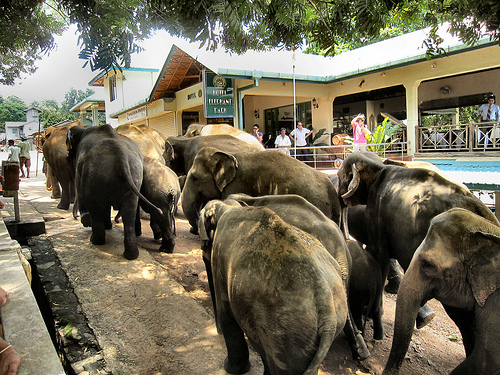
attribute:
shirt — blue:
[475, 101, 498, 121]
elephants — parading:
[45, 79, 474, 358]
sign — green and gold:
[202, 74, 233, 121]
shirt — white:
[290, 127, 311, 144]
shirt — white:
[273, 134, 291, 146]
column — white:
[400, 81, 420, 149]